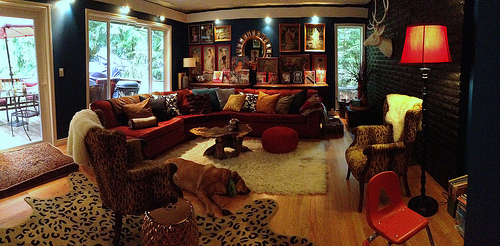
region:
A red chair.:
[343, 166, 439, 242]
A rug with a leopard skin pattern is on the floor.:
[1, 165, 316, 242]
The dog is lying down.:
[155, 150, 260, 220]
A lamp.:
[386, 21, 456, 221]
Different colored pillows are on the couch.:
[115, 70, 317, 137]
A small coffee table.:
[181, 105, 258, 156]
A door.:
[0, 0, 60, 165]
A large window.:
[75, 10, 175, 100]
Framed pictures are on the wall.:
[182, 20, 332, 80]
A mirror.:
[231, 26, 273, 66]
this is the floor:
[293, 197, 346, 227]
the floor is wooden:
[293, 200, 336, 229]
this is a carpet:
[265, 164, 303, 189]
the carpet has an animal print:
[51, 207, 84, 230]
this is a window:
[90, 26, 165, 66]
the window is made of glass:
[108, 47, 149, 68]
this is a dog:
[174, 157, 252, 217]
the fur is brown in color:
[188, 164, 204, 176]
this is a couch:
[95, 88, 324, 145]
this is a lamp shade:
[391, 20, 468, 211]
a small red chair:
[344, 166, 434, 239]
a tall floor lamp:
[388, 9, 463, 219]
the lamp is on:
[385, 4, 450, 107]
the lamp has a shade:
[382, 8, 455, 90]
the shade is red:
[385, 14, 462, 110]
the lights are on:
[99, 0, 337, 27]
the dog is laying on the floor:
[152, 141, 267, 210]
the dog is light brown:
[155, 143, 257, 208]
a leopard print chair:
[343, 80, 425, 171]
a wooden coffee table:
[180, 108, 254, 158]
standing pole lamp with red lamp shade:
[400, 22, 452, 216]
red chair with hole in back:
[363, 170, 435, 245]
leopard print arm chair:
[344, 91, 422, 213]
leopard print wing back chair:
[78, 108, 180, 244]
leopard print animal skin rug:
[1, 167, 315, 244]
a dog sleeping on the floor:
[162, 157, 251, 219]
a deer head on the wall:
[361, 0, 393, 59]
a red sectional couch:
[91, 86, 321, 160]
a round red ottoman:
[260, 124, 297, 153]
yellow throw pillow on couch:
[255, 90, 280, 114]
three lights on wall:
[206, 9, 333, 29]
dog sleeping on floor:
[160, 152, 252, 214]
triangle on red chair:
[367, 182, 394, 219]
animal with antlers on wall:
[360, 4, 402, 61]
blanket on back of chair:
[62, 102, 114, 177]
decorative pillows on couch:
[180, 87, 311, 121]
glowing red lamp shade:
[395, 17, 452, 76]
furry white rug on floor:
[180, 134, 334, 196]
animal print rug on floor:
[35, 173, 100, 240]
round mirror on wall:
[227, 29, 272, 66]